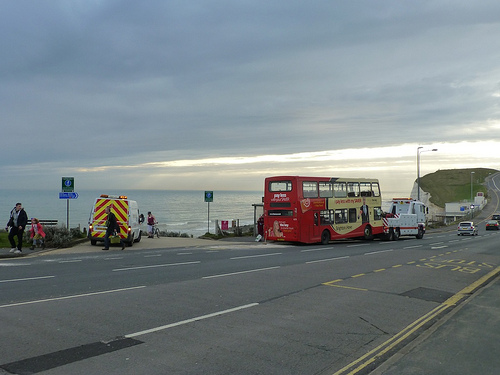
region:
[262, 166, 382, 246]
a red and yellow double decker bus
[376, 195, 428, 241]
a white tow truck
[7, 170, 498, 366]
a long paved road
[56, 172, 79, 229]
a traffic information sign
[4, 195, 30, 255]
a man walking on sidewalk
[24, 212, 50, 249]
a chlid waking on sidewalk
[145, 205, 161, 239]
a man with bicycle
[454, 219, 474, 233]
white car on street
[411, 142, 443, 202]
an overhead street light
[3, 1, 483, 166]
a cloudy grey sky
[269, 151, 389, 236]
bus has 2 levels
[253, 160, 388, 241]
bus is red and yellow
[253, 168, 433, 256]
bus is being towed by truck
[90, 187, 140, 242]
van has striped doors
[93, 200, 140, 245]
the doors are yellow and red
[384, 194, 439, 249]
tow truck is white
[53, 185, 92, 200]
the sign is blue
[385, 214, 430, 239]
red stripe on truck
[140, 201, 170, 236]
person standing in front of van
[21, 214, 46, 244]
girl's jacket is pink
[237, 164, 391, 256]
the bus is red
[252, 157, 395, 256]
the bus is tall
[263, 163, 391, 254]
the bus is yellow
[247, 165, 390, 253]
the bus is being towed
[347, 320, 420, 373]
the lines are yellow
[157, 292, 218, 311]
the road is black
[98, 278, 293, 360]
the line is white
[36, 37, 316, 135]
the sky is dreary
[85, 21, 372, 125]
the sky is cloudy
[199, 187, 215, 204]
the sign is square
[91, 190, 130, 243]
yellow and red diagonal stripes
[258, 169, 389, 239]
red and yellow double decker bus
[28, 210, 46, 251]
little girl in pink coat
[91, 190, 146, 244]
white truck with yellow and red back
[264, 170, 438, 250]
double decker bus being towed away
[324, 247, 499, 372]
yellow lines on road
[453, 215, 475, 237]
white car in front of tow truck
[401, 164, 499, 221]
grass patch above cliff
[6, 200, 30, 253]
man in black jacket and pants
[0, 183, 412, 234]
view of water in left background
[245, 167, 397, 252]
A bus is parked on the street.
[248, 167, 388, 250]
The bus is red and yellow.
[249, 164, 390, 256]
The bus is a double decker bus.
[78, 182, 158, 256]
An ambulance is parked.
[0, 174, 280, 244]
A body of water is in the background.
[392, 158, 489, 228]
A cliff is in the background.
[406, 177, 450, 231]
The cliff's side is white.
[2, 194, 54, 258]
A man and child are walking.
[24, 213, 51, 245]
The child's coat is pink.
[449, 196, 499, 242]
Cars drive on the street.